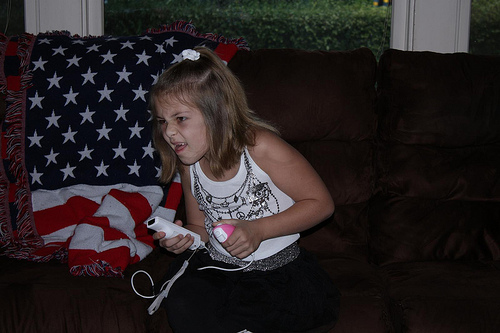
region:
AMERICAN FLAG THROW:
[26, 27, 244, 284]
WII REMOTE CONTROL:
[128, 207, 208, 315]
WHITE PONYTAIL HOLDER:
[177, 46, 203, 63]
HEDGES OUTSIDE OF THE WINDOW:
[81, 0, 406, 57]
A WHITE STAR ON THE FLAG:
[39, 103, 68, 132]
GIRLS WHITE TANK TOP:
[183, 145, 305, 270]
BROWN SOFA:
[4, 32, 495, 331]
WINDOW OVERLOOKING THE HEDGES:
[3, 0, 498, 60]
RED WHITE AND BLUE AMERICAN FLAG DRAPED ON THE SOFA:
[0, 27, 242, 277]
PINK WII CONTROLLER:
[208, 217, 250, 259]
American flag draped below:
[27, 49, 188, 290]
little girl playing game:
[156, 39, 337, 324]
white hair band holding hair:
[173, 35, 228, 85]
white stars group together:
[39, 39, 157, 171]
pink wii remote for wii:
[216, 216, 273, 273]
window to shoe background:
[110, 3, 398, 44]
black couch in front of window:
[244, 58, 496, 329]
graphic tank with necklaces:
[187, 176, 298, 258]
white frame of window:
[395, 7, 473, 55]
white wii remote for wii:
[144, 209, 213, 301]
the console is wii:
[137, 206, 219, 253]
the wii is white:
[131, 210, 208, 320]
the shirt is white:
[185, 171, 292, 277]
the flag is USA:
[39, 55, 134, 241]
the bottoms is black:
[183, 255, 356, 331]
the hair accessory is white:
[177, 45, 204, 70]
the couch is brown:
[342, 120, 494, 283]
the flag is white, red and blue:
[22, 83, 114, 239]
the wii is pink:
[206, 215, 258, 269]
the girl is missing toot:
[157, 131, 204, 164]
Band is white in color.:
[181, 45, 211, 65]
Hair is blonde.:
[173, 68, 247, 113]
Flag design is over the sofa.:
[45, 93, 140, 214]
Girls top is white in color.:
[193, 171, 273, 218]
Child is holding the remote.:
[136, 213, 256, 270]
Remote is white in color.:
[144, 207, 211, 250]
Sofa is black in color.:
[333, 80, 478, 202]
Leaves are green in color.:
[238, 13, 358, 37]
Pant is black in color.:
[194, 281, 294, 320]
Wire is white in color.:
[136, 259, 216, 314]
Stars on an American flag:
[128, 31, 195, 106]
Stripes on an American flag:
[28, 188, 137, 257]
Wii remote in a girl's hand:
[146, 215, 197, 254]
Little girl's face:
[139, 77, 288, 184]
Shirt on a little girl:
[186, 158, 353, 282]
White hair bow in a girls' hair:
[156, 41, 227, 81]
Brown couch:
[247, 45, 489, 268]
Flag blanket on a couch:
[21, 44, 195, 302]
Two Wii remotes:
[131, 209, 281, 282]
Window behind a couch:
[106, 4, 401, 53]